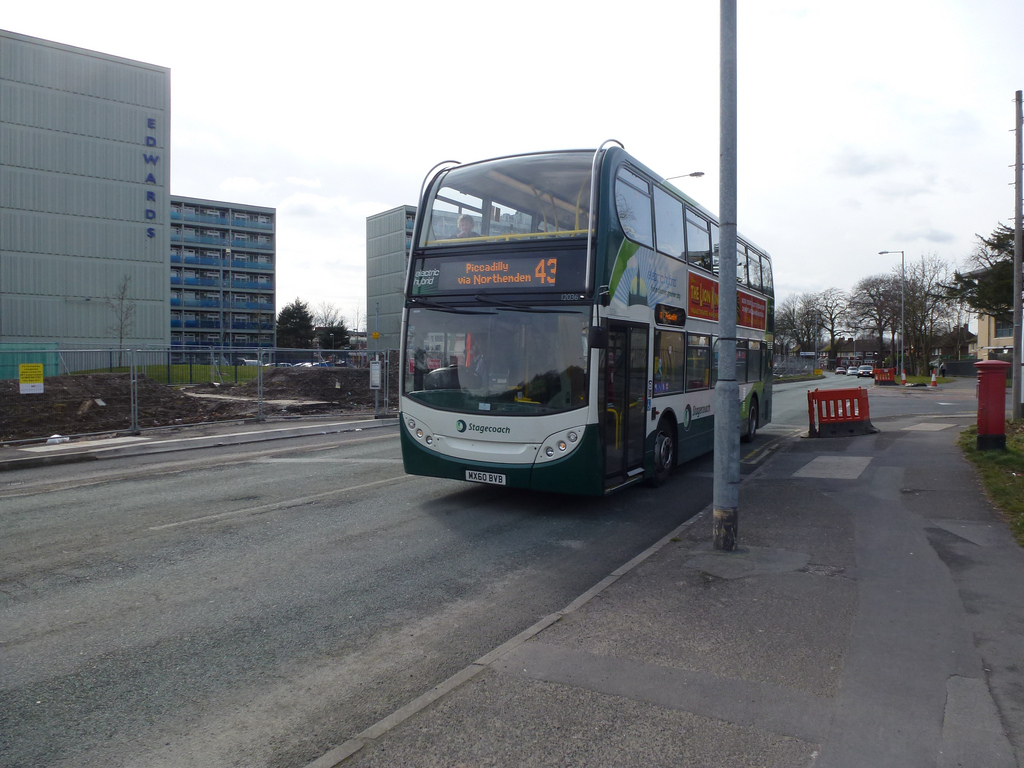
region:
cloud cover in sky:
[0, 3, 1021, 346]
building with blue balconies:
[169, 194, 275, 362]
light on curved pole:
[872, 247, 910, 381]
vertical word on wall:
[5, 27, 173, 383]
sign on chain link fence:
[0, 342, 133, 441]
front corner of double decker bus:
[393, 148, 771, 503]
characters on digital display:
[431, 254, 559, 286]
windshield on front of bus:
[398, 308, 594, 492]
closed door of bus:
[601, 321, 650, 483]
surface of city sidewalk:
[323, 408, 1017, 764]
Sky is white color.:
[204, 48, 536, 156]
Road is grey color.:
[81, 486, 361, 665]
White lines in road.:
[22, 429, 437, 575]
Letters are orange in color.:
[423, 245, 583, 294]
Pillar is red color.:
[942, 339, 1020, 464]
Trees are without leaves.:
[793, 267, 958, 384]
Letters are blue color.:
[144, 102, 165, 259]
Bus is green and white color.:
[403, 156, 742, 485]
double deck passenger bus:
[404, 116, 806, 550]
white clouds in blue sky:
[286, 20, 328, 72]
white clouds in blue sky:
[198, 104, 246, 143]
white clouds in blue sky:
[808, 126, 873, 200]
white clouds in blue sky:
[878, 37, 959, 115]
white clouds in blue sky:
[784, 169, 851, 218]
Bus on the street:
[366, 120, 863, 520]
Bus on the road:
[372, 123, 799, 506]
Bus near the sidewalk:
[389, 138, 788, 532]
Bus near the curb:
[376, 158, 811, 516]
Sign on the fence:
[10, 356, 69, 401]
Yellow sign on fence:
[10, 350, 56, 402]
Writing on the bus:
[439, 411, 532, 441]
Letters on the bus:
[448, 414, 535, 438]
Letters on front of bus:
[449, 402, 529, 447]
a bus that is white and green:
[389, 142, 839, 519]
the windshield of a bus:
[400, 303, 593, 411]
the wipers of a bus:
[409, 291, 596, 308]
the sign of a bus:
[433, 253, 585, 311]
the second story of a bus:
[433, 127, 763, 317]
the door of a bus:
[596, 335, 642, 487]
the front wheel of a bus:
[631, 414, 698, 487]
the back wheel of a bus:
[737, 385, 777, 487]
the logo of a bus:
[438, 405, 525, 454]